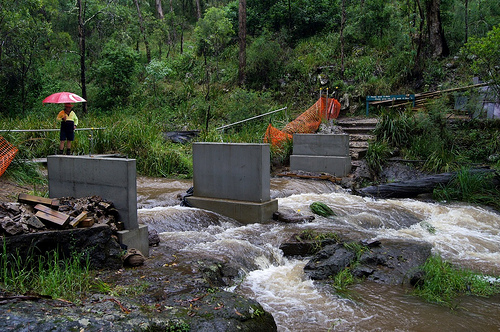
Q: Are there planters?
A: No, there are no planters.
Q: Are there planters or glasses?
A: No, there are no planters or glasses.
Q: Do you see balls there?
A: No, there are no balls.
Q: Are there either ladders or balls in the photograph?
A: No, there are no balls or ladders.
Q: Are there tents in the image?
A: No, there are no tents.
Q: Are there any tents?
A: No, there are no tents.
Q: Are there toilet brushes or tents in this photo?
A: No, there are no tents or toilet brushes.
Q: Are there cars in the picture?
A: No, there are no cars.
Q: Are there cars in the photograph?
A: No, there are no cars.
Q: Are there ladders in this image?
A: No, there are no ladders.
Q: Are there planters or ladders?
A: No, there are no ladders or planters.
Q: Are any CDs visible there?
A: No, there are no cds.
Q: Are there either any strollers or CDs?
A: No, there are no CDs or strollers.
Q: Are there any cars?
A: No, there are no cars.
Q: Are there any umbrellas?
A: Yes, there is an umbrella.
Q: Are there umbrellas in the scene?
A: Yes, there is an umbrella.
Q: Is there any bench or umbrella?
A: Yes, there is an umbrella.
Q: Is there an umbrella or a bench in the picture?
A: Yes, there is an umbrella.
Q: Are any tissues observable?
A: No, there are no tissues.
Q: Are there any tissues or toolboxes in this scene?
A: No, there are no tissues or toolboxes.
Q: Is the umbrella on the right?
A: No, the umbrella is on the left of the image.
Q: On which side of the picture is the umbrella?
A: The umbrella is on the left of the image.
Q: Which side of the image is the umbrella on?
A: The umbrella is on the left of the image.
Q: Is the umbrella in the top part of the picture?
A: Yes, the umbrella is in the top of the image.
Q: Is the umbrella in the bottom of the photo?
A: No, the umbrella is in the top of the image.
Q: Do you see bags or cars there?
A: No, there are no cars or bags.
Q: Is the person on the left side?
A: Yes, the person is on the left of the image.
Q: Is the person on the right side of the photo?
A: No, the person is on the left of the image.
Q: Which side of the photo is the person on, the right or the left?
A: The person is on the left of the image.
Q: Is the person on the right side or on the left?
A: The person is on the left of the image.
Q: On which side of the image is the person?
A: The person is on the left of the image.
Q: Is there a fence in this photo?
A: Yes, there is a fence.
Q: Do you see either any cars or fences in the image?
A: Yes, there is a fence.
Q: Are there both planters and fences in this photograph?
A: No, there is a fence but no planters.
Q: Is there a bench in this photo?
A: No, there are no benches.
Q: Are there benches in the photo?
A: No, there are no benches.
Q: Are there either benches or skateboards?
A: No, there are no benches or skateboards.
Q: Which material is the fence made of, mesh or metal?
A: The fence is made of mesh.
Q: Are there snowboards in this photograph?
A: No, there are no snowboards.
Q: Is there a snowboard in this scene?
A: No, there are no snowboards.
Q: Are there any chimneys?
A: No, there are no chimneys.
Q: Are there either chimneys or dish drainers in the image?
A: No, there are no chimneys or dish drainers.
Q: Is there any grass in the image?
A: Yes, there is grass.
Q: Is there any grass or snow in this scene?
A: Yes, there is grass.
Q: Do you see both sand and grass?
A: No, there is grass but no sand.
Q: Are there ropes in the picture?
A: No, there are no ropes.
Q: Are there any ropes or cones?
A: No, there are no ropes or cones.